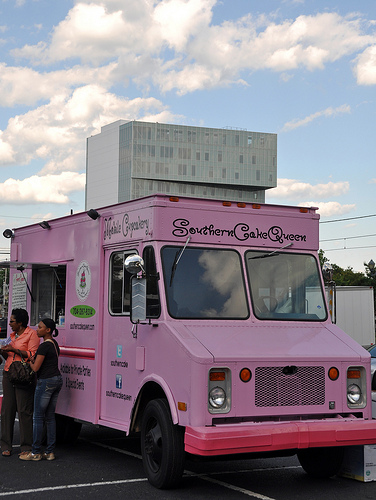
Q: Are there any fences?
A: No, there are no fences.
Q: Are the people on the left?
A: Yes, the people are on the left of the image.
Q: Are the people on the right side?
A: No, the people are on the left of the image.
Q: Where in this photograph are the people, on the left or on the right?
A: The people are on the left of the image.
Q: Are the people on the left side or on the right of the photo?
A: The people are on the left of the image.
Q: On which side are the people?
A: The people are on the left of the image.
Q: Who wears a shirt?
A: The people wear a shirt.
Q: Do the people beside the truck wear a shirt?
A: Yes, the people wear a shirt.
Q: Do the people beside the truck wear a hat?
A: No, the people wear a shirt.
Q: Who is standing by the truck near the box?
A: The people are standing by the truck.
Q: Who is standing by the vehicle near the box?
A: The people are standing by the truck.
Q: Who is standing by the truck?
A: The people are standing by the truck.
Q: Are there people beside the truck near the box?
A: Yes, there are people beside the truck.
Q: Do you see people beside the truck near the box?
A: Yes, there are people beside the truck.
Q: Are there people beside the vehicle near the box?
A: Yes, there are people beside the truck.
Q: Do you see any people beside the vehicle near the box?
A: Yes, there are people beside the truck.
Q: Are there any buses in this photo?
A: No, there are no buses.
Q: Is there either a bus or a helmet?
A: No, there are no buses or helmets.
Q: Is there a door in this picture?
A: Yes, there is a door.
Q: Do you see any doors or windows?
A: Yes, there is a door.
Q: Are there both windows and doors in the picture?
A: Yes, there are both a door and a window.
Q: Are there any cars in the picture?
A: No, there are no cars.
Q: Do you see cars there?
A: No, there are no cars.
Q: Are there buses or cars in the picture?
A: No, there are no cars or buses.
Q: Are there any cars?
A: No, there are no cars.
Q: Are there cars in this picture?
A: No, there are no cars.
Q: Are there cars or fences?
A: No, there are no cars or fences.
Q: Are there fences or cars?
A: No, there are no cars or fences.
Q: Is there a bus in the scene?
A: No, there are no buses.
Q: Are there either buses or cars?
A: No, there are no buses or cars.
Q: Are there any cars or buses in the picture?
A: No, there are no buses or cars.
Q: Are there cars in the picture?
A: No, there are no cars.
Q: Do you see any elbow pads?
A: No, there are no elbow pads.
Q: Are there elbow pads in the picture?
A: No, there are no elbow pads.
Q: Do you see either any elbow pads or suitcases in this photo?
A: No, there are no elbow pads or suitcases.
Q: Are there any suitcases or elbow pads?
A: No, there are no elbow pads or suitcases.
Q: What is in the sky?
A: The clouds are in the sky.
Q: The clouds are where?
A: The clouds are in the sky.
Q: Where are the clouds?
A: The clouds are in the sky.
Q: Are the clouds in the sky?
A: Yes, the clouds are in the sky.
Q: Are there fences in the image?
A: No, there are no fences.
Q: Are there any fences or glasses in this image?
A: No, there are no fences or glasses.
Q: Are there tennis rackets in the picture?
A: No, there are no tennis rackets.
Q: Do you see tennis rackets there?
A: No, there are no tennis rackets.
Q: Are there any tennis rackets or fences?
A: No, there are no tennis rackets or fences.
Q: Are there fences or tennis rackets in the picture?
A: No, there are no tennis rackets or fences.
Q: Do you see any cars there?
A: No, there are no cars.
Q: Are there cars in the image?
A: No, there are no cars.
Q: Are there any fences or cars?
A: No, there are no cars or fences.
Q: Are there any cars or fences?
A: No, there are no cars or fences.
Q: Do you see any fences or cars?
A: No, there are no cars or fences.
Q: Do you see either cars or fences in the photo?
A: No, there are no cars or fences.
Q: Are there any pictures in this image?
A: No, there are no pictures.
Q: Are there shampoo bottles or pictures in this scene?
A: No, there are no pictures or shampoo bottles.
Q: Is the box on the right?
A: Yes, the box is on the right of the image.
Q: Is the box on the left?
A: No, the box is on the right of the image.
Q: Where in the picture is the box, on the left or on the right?
A: The box is on the right of the image.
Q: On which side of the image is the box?
A: The box is on the right of the image.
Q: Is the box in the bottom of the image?
A: Yes, the box is in the bottom of the image.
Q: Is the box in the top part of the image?
A: No, the box is in the bottom of the image.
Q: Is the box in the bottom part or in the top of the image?
A: The box is in the bottom of the image.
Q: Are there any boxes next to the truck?
A: Yes, there is a box next to the truck.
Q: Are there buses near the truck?
A: No, there is a box near the truck.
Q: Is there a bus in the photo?
A: No, there are no buses.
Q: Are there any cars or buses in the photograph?
A: No, there are no buses or cars.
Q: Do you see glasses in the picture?
A: No, there are no glasses.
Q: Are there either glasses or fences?
A: No, there are no glasses or fences.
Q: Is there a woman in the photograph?
A: Yes, there is a woman.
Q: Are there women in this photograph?
A: Yes, there is a woman.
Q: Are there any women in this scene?
A: Yes, there is a woman.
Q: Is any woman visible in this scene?
A: Yes, there is a woman.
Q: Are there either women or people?
A: Yes, there is a woman.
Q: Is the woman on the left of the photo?
A: Yes, the woman is on the left of the image.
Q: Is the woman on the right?
A: No, the woman is on the left of the image.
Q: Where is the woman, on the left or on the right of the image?
A: The woman is on the left of the image.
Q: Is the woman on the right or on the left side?
A: The woman is on the left of the image.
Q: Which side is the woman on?
A: The woman is on the left of the image.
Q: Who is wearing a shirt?
A: The woman is wearing a shirt.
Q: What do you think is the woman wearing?
A: The woman is wearing a shirt.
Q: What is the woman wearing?
A: The woman is wearing a shirt.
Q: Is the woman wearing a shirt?
A: Yes, the woman is wearing a shirt.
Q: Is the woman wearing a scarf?
A: No, the woman is wearing a shirt.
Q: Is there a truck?
A: Yes, there is a truck.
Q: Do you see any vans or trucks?
A: Yes, there is a truck.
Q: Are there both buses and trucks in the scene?
A: No, there is a truck but no buses.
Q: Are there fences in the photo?
A: No, there are no fences.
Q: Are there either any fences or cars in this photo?
A: No, there are no fences or cars.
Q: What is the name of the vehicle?
A: The vehicle is a truck.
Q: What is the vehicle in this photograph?
A: The vehicle is a truck.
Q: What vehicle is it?
A: The vehicle is a truck.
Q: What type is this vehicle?
A: This is a truck.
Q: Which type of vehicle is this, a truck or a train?
A: This is a truck.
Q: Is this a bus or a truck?
A: This is a truck.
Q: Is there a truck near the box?
A: Yes, there is a truck near the box.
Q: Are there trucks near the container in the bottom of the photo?
A: Yes, there is a truck near the box.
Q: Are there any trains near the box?
A: No, there is a truck near the box.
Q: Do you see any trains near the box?
A: No, there is a truck near the box.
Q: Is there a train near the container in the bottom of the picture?
A: No, there is a truck near the box.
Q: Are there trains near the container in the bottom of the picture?
A: No, there is a truck near the box.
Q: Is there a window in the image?
A: Yes, there is a window.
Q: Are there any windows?
A: Yes, there is a window.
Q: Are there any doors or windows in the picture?
A: Yes, there is a window.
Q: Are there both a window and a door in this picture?
A: Yes, there are both a window and a door.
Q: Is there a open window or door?
A: Yes, there is an open window.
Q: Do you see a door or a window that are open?
A: Yes, the window is open.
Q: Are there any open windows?
A: Yes, there is an open window.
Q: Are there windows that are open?
A: Yes, there is a window that is open.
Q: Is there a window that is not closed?
A: Yes, there is a open window.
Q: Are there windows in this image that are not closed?
A: Yes, there is a open window.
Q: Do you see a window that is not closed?
A: Yes, there is a open window.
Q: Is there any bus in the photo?
A: No, there are no buses.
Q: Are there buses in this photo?
A: No, there are no buses.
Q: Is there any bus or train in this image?
A: No, there are no buses or trains.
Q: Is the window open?
A: Yes, the window is open.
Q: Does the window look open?
A: Yes, the window is open.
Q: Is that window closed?
A: No, the window is open.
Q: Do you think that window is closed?
A: No, the window is open.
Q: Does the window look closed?
A: No, the window is open.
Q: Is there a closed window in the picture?
A: No, there is a window but it is open.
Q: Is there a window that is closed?
A: No, there is a window but it is open.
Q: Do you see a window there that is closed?
A: No, there is a window but it is open.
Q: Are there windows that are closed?
A: No, there is a window but it is open.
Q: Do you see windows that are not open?
A: No, there is a window but it is open.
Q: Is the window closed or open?
A: The window is open.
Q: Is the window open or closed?
A: The window is open.